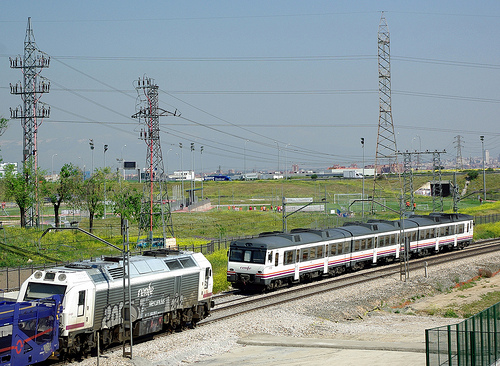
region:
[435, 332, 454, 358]
the fence is black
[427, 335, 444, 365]
the fence is black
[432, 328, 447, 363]
the fence is black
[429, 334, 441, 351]
the fence is black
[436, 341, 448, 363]
the fence is black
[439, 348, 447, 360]
the fence is black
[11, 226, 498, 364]
these are rail roads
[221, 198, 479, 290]
this is a train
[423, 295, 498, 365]
this is a fence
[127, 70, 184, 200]
this is a power tower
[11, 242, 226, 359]
this is a short train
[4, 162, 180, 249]
these are green trees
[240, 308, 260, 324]
these are gray gravels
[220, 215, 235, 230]
this is green grass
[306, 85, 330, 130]
this is blue sky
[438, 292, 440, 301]
this is the dirt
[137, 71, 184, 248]
Metal utility pole at a train track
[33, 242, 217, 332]
Engine at the back of a train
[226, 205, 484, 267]
Passenger train with three cars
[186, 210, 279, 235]
Green grass behind a train track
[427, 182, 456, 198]
Tunnel entrance in hill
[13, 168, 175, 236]
Trees growing by a train track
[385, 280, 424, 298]
Gravel in the hill of a train track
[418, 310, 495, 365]
Green fence near a train track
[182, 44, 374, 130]
Power lines in the sky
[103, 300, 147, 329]
Graffiti on a train engine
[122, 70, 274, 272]
Light post on the ground.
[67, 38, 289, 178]
Wires between the poles.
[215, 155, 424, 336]
Train on the track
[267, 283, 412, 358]
Gravel on the track.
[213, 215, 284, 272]
Windows on the train.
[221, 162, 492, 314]
Grass behind the train.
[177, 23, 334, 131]
Blue sky above the trains.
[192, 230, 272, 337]
Rails under the train.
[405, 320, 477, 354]
Green fence in the background.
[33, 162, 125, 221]
Trees on the ground.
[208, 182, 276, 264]
the train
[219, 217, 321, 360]
the train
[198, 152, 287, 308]
the train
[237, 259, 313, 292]
the train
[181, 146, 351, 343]
the train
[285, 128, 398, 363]
the train